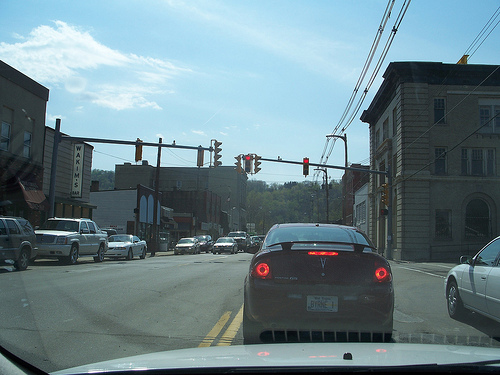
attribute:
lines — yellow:
[206, 250, 233, 259]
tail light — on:
[255, 260, 270, 278]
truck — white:
[8, 225, 28, 254]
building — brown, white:
[78, 176, 175, 268]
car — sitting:
[238, 219, 404, 333]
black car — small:
[252, 205, 407, 335]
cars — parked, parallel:
[37, 215, 108, 262]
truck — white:
[39, 211, 111, 261]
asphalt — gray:
[76, 292, 123, 352]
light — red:
[247, 255, 277, 280]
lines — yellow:
[192, 299, 264, 347]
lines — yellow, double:
[195, 328, 230, 347]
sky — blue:
[2, 0, 499, 175]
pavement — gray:
[2, 244, 498, 371]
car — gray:
[441, 231, 497, 332]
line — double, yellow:
[194, 285, 261, 357]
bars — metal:
[152, 137, 173, 189]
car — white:
[230, 190, 410, 363]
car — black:
[246, 222, 395, 337]